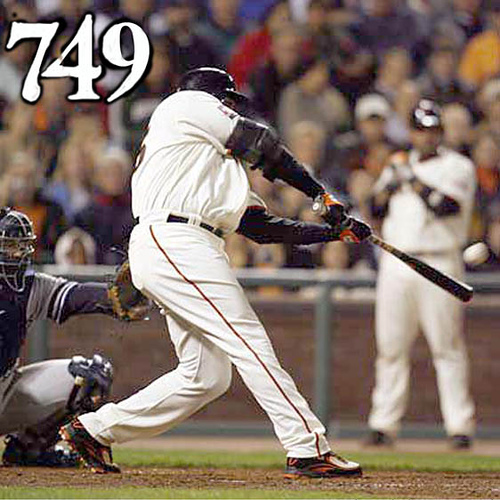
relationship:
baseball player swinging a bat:
[60, 65, 373, 477] [311, 198, 475, 302]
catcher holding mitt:
[0, 206, 153, 466] [107, 256, 156, 321]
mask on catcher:
[0, 209, 35, 294] [0, 206, 153, 466]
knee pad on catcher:
[68, 355, 113, 412] [0, 206, 153, 466]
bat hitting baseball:
[311, 198, 475, 302] [462, 241, 489, 267]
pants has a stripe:
[76, 211, 331, 461] [148, 224, 323, 458]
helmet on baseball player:
[172, 66, 251, 102] [58, 65, 373, 477]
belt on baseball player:
[133, 216, 223, 239] [58, 65, 373, 477]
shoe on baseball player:
[58, 416, 122, 475] [58, 65, 373, 477]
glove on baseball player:
[320, 189, 346, 227] [58, 65, 373, 477]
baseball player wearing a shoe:
[58, 65, 373, 477] [58, 416, 122, 475]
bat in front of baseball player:
[311, 198, 475, 302] [58, 65, 373, 477]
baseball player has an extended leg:
[58, 65, 373, 477] [129, 224, 363, 479]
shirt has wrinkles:
[131, 91, 249, 236] [131, 89, 250, 236]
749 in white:
[6, 12, 151, 104] [5, 13, 151, 104]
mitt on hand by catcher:
[107, 256, 156, 321] [0, 206, 153, 466]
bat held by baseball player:
[311, 198, 475, 302] [58, 65, 373, 477]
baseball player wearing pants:
[58, 65, 373, 477] [76, 211, 331, 461]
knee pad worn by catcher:
[68, 355, 113, 412] [0, 206, 153, 466]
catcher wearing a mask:
[0, 206, 153, 466] [0, 209, 35, 294]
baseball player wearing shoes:
[58, 65, 373, 477] [60, 417, 363, 480]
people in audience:
[0, 0, 499, 302] [0, 0, 499, 299]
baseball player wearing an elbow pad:
[58, 65, 373, 477] [226, 115, 308, 186]